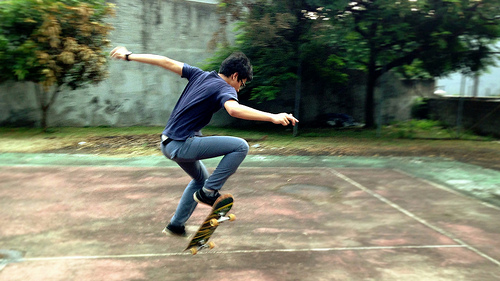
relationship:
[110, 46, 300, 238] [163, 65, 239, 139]
man has shirt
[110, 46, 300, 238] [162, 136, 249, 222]
man has pants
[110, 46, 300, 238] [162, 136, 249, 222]
man ha pants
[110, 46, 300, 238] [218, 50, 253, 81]
man has hair